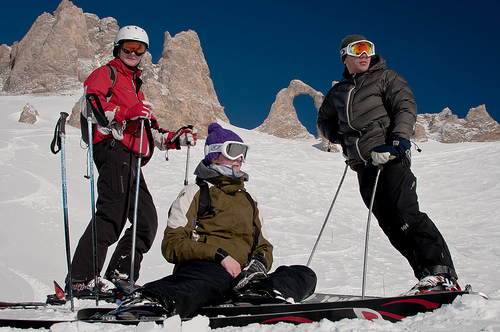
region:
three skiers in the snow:
[65, 23, 462, 313]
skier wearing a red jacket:
[64, 26, 198, 298]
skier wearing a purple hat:
[103, 122, 316, 325]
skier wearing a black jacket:
[317, 32, 463, 294]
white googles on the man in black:
[338, 33, 376, 62]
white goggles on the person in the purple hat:
[202, 139, 250, 161]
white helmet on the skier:
[112, 25, 149, 50]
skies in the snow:
[0, 298, 484, 327]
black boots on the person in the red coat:
[64, 276, 142, 299]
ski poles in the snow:
[53, 111, 396, 315]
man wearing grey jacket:
[320, 32, 420, 187]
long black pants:
[352, 155, 472, 303]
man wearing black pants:
[325, 33, 475, 318]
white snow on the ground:
[247, 148, 353, 246]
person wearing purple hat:
[195, 117, 242, 180]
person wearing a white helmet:
[80, 25, 154, 148]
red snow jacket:
[75, 43, 192, 180]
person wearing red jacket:
[54, 37, 175, 292]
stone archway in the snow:
[257, 73, 335, 158]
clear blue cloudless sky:
[218, 8, 330, 85]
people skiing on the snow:
[52, 27, 389, 299]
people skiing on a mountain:
[59, 16, 464, 323]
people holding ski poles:
[51, 45, 499, 325]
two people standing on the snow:
[15, 14, 460, 329]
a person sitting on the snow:
[74, 88, 307, 330]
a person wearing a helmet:
[83, 16, 213, 111]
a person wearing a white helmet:
[83, 12, 160, 82]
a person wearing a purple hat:
[189, 112, 318, 249]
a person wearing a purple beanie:
[214, 107, 272, 222]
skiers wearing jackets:
[75, 20, 447, 328]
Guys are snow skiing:
[26, 20, 482, 317]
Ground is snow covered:
[250, 125, 347, 252]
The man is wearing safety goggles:
[328, 30, 400, 62]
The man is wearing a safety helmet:
[84, 13, 164, 43]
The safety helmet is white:
[97, 14, 164, 52]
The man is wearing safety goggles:
[92, 33, 154, 58]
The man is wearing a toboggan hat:
[198, 115, 249, 161]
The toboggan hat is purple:
[197, 115, 257, 163]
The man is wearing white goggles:
[199, 129, 275, 164]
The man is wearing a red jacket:
[70, 54, 172, 158]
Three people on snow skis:
[68, 22, 463, 297]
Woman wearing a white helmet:
[113, 23, 149, 49]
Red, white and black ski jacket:
[85, 57, 171, 165]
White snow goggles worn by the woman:
[200, 140, 250, 162]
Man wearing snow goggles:
[333, 39, 377, 60]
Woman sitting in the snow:
[162, 125, 317, 303]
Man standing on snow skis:
[293, 35, 465, 297]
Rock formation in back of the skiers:
[1, 0, 230, 136]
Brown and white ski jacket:
[161, 162, 274, 275]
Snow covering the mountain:
[0, 92, 497, 328]